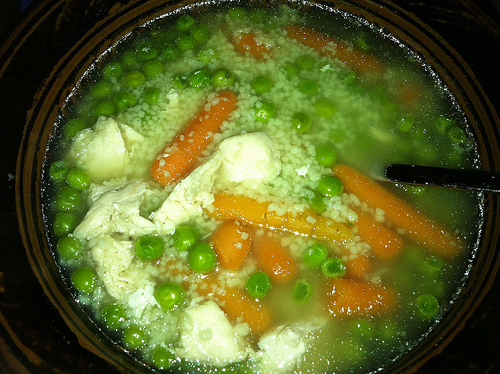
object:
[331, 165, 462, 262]
carrot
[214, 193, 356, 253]
carrot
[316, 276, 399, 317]
carrot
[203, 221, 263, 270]
carrot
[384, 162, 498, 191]
spoon handle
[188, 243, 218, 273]
pea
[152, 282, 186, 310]
pea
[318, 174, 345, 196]
pea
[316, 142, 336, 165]
pea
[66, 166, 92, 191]
pea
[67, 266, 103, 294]
peas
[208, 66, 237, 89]
peas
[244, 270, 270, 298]
pea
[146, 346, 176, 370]
pea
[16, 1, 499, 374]
bowl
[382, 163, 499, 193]
spoon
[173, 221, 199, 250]
pea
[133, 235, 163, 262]
pea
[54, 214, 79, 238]
pea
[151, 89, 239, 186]
carrot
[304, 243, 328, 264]
peas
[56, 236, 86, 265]
peas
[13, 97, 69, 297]
edge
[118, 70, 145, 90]
pea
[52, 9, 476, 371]
mixture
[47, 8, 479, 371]
broth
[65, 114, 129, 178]
chunk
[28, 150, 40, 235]
stripes